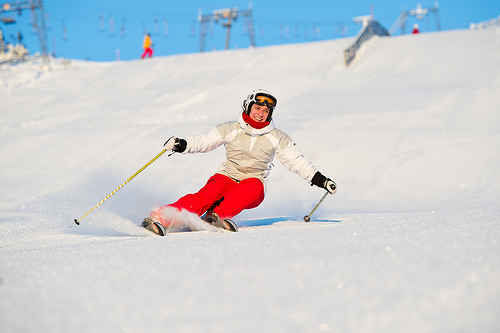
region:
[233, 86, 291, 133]
WOMAN WEARING SKI HELMET AND GOGGLES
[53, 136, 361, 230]
TWO YELLOW AND WHITE SKI POLES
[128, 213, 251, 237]
TIPS OF SKIS IN THE SNOW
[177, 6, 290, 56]
SKI LIFT TOWER NEAR THE SKI RUN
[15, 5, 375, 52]
SKI LIFT WITH LIFT CHAIRS ATTACHED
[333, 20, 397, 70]
FENCE GOING DOWN HILL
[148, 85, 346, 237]
WOMAN DRESSED IN SKIING GEAR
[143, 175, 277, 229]
BRIGHT RED INSULATED SKI PANTS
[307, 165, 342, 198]
BLACK AND WHITE WINTER GLOVE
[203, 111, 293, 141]
RED SCARF AROUNG WOMAN'S NECK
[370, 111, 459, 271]
The snow is the color white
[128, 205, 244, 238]
The woman has on snow skis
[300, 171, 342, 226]
The woman is holding the ski stick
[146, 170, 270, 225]
The woman is wearing pants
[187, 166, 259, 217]
The color of the pants are red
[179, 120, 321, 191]
The woman is wearing a white and beige jacket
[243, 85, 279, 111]
The woman is wearing snow goggles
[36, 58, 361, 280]
The woman is skiing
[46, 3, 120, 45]
The sky is clear and blue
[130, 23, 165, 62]
The person is walking on the ice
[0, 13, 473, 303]
A person is doing some skiing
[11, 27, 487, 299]
A person is skiing down the slope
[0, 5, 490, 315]
A person is at a ski resort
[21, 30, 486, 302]
A person is having some fun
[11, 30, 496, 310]
A person is enjoying the snow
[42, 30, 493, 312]
The person is enjoying their day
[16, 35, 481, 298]
The person is wearing a helmet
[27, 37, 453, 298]
The person has goggles on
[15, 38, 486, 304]
The person is holding ski poles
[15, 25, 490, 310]
A person is skiing to the Lodge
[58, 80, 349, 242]
THE WOMAN IS ON THE SNOWY HILL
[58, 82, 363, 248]
THE WOMAN IS SKIING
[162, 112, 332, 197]
THE WOMAN IS WEARING A WHITE JACKET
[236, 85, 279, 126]
THE WOMAN IS WEARING A WHITE HAT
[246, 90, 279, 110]
THE WOMAN IS WEARING GOGGLES ON HER HEAD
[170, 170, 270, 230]
THE WOMAN IS WEARING RED PANTS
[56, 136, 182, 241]
THE POLE IS YELLOW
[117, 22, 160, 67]
THE MAN IS AT THE TOP OF THE HILL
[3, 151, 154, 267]
THE SNOW IS FLYING THROUGH THE AIR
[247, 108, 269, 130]
THE WOMAN IS SMILING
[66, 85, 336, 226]
A woman skiing in the snow.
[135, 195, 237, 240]
A pair of skis.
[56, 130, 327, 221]
A pair of yellow and black ski poles.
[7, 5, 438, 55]
A ski lift.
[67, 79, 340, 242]
A woman on skis smiling.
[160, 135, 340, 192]
Black and white winter gloves.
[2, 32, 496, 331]
The white snow.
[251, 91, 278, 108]
A pair of ski goggles.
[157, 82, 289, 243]
A woman with ski goggles on her head.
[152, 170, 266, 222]
A pair of red ski pants.